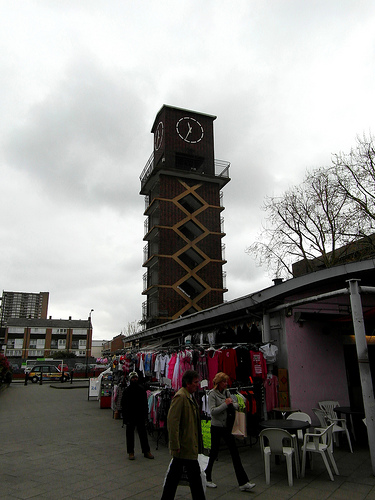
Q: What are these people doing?
A: Shopping.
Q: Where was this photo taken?
A: At a swapmeet.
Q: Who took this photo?
A: A tourist.